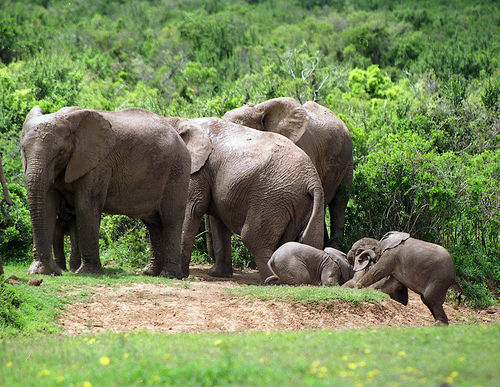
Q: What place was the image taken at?
A: It was taken at the field.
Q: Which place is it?
A: It is a field.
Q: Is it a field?
A: Yes, it is a field.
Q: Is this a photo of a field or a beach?
A: It is showing a field.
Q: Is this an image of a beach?
A: No, the picture is showing a field.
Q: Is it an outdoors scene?
A: Yes, it is outdoors.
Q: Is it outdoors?
A: Yes, it is outdoors.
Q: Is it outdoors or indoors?
A: It is outdoors.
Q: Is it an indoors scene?
A: No, it is outdoors.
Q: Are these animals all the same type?
A: Yes, all the animals are elephants.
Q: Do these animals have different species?
A: No, all the animals are elephants.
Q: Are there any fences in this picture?
A: No, there are no fences.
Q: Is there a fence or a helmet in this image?
A: No, there are no fences or helmets.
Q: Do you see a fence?
A: No, there are no fences.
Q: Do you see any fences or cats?
A: No, there are no fences or cats.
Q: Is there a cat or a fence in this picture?
A: No, there are no fences or cats.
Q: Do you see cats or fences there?
A: No, there are no fences or cats.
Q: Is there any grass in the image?
A: Yes, there is grass.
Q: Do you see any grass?
A: Yes, there is grass.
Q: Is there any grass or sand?
A: Yes, there is grass.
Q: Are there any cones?
A: No, there are no cones.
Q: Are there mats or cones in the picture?
A: No, there are no cones or mats.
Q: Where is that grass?
A: The grass is in the field.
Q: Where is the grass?
A: The grass is in the field.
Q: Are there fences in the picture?
A: No, there are no fences.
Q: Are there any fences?
A: No, there are no fences.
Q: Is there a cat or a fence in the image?
A: No, there are no fences or cats.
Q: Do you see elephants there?
A: Yes, there is an elephant.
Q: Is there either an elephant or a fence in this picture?
A: Yes, there is an elephant.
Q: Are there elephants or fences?
A: Yes, there is an elephant.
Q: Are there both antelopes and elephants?
A: No, there is an elephant but no antelopes.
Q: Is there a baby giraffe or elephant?
A: Yes, there is a baby elephant.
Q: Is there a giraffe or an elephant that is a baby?
A: Yes, the elephant is a baby.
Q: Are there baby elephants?
A: Yes, there is a baby elephant.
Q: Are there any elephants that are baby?
A: Yes, there is an elephant that is a baby.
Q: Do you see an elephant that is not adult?
A: Yes, there is an baby elephant.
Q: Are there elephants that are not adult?
A: Yes, there is an baby elephant.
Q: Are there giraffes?
A: No, there are no giraffes.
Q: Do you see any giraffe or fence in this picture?
A: No, there are no giraffes or fences.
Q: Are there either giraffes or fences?
A: No, there are no giraffes or fences.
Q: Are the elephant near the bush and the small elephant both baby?
A: Yes, both the elephant and the elephant are baby.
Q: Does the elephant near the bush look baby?
A: Yes, the elephant is a baby.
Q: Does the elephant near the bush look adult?
A: No, the elephant is a baby.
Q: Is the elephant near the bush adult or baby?
A: The elephant is a baby.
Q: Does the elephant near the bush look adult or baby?
A: The elephant is a baby.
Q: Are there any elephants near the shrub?
A: Yes, there is an elephant near the shrub.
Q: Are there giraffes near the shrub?
A: No, there is an elephant near the shrub.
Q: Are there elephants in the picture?
A: Yes, there is an elephant.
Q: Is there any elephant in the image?
A: Yes, there is an elephant.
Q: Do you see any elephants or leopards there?
A: Yes, there is an elephant.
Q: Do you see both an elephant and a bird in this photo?
A: No, there is an elephant but no birds.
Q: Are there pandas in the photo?
A: No, there are no pandas.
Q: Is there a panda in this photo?
A: No, there are no pandas.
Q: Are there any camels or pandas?
A: No, there are no pandas or camels.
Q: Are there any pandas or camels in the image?
A: No, there are no pandas or camels.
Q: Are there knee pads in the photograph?
A: No, there are no knee pads.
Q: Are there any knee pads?
A: No, there are no knee pads.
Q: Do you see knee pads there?
A: No, there are no knee pads.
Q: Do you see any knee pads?
A: No, there are no knee pads.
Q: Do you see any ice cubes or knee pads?
A: No, there are no knee pads or ice cubes.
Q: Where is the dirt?
A: The dirt is on the field.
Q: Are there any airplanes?
A: No, there are no airplanes.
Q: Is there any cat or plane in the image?
A: No, there are no airplanes or cats.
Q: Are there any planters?
A: No, there are no planters.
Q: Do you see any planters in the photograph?
A: No, there are no planters.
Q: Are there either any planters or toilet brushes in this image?
A: No, there are no planters or toilet brushes.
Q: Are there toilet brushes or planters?
A: No, there are no planters or toilet brushes.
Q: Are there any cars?
A: No, there are no cars.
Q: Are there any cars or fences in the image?
A: No, there are no cars or fences.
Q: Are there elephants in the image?
A: Yes, there is an elephant.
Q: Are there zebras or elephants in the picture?
A: Yes, there is an elephant.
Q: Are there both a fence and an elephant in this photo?
A: No, there is an elephant but no fences.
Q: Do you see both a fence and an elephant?
A: No, there is an elephant but no fences.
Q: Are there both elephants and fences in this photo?
A: No, there is an elephant but no fences.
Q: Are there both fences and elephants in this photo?
A: No, there is an elephant but no fences.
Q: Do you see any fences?
A: No, there are no fences.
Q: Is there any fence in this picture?
A: No, there are no fences.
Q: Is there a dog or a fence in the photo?
A: No, there are no fences or dogs.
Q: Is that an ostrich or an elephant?
A: That is an elephant.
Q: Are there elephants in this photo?
A: Yes, there is an elephant.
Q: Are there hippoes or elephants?
A: Yes, there is an elephant.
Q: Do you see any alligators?
A: No, there are no alligators.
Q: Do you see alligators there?
A: No, there are no alligators.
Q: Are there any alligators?
A: No, there are no alligators.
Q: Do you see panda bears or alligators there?
A: No, there are no alligators or panda bears.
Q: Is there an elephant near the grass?
A: Yes, there is an elephant near the grass.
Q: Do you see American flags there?
A: No, there are no American flags.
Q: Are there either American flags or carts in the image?
A: No, there are no American flags or carts.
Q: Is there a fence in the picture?
A: No, there are no fences.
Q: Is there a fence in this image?
A: No, there are no fences.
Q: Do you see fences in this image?
A: No, there are no fences.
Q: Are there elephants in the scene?
A: Yes, there is an elephant.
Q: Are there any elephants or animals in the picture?
A: Yes, there is an elephant.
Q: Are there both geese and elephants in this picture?
A: No, there is an elephant but no geese.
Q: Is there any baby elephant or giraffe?
A: Yes, there is a baby elephant.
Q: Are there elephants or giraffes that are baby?
A: Yes, the elephant is a baby.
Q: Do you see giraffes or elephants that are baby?
A: Yes, the elephant is a baby.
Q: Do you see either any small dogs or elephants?
A: Yes, there is a small elephant.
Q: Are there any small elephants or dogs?
A: Yes, there is a small elephant.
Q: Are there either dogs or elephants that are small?
A: Yes, the elephant is small.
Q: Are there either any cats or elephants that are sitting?
A: Yes, the elephant is sitting.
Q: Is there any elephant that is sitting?
A: Yes, there is an elephant that is sitting.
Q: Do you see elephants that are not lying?
A: Yes, there is an elephant that is sitting .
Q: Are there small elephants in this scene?
A: Yes, there is a small elephant.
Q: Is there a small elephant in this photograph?
A: Yes, there is a small elephant.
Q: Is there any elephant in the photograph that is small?
A: Yes, there is an elephant that is small.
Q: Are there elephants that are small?
A: Yes, there is an elephant that is small.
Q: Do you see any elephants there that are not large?
A: Yes, there is a small elephant.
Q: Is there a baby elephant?
A: Yes, there is a baby elephant.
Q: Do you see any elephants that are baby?
A: Yes, there is a baby elephant.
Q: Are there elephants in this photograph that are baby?
A: Yes, there is an elephant that is a baby.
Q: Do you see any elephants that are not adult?
A: Yes, there is an baby elephant.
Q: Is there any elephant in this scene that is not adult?
A: Yes, there is an baby elephant.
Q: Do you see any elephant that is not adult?
A: Yes, there is an baby elephant.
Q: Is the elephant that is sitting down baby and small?
A: Yes, the elephant is a baby and small.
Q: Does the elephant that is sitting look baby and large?
A: No, the elephant is a baby but small.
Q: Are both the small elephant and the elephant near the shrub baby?
A: Yes, both the elephant and the elephant are baby.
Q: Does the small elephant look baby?
A: Yes, the elephant is a baby.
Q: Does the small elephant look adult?
A: No, the elephant is a baby.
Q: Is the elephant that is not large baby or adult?
A: The elephant is a baby.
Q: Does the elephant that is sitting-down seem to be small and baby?
A: Yes, the elephant is small and baby.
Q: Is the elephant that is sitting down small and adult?
A: No, the elephant is small but baby.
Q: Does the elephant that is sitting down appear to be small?
A: Yes, the elephant is small.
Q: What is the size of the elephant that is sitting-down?
A: The elephant is small.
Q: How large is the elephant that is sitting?
A: The elephant is small.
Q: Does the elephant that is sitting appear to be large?
A: No, the elephant is small.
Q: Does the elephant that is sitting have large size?
A: No, the elephant is small.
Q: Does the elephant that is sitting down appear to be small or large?
A: The elephant is small.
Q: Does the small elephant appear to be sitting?
A: Yes, the elephant is sitting.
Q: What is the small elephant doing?
A: The elephant is sitting.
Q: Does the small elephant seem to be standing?
A: No, the elephant is sitting.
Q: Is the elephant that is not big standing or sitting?
A: The elephant is sitting.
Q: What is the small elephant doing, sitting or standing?
A: The elephant is sitting.